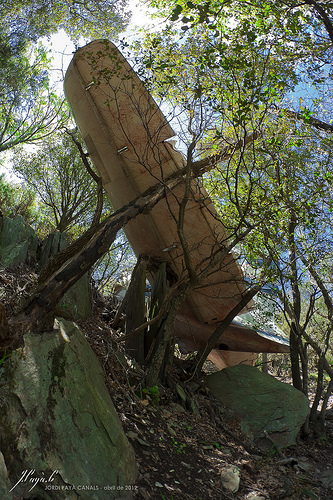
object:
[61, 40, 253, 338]
rock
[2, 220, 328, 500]
hillside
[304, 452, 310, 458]
leaves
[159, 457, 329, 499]
dirt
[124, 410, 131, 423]
leaves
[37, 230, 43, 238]
leaves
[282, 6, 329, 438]
tree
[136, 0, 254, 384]
tree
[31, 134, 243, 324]
tree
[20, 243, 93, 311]
trunk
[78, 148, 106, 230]
trunk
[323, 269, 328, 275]
leaf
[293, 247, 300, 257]
brances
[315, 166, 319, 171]
leaf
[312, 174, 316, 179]
leaf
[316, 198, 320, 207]
leaf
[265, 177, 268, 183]
leaf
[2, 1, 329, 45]
sky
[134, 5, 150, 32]
cloud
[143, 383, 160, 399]
mass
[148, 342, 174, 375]
base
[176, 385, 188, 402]
mass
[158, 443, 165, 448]
leaf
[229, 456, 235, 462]
leaf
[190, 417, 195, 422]
leaf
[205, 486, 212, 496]
leaf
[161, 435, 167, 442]
leaf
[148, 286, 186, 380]
trunk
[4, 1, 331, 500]
picture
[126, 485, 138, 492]
2012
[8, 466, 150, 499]
watermark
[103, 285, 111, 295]
weeds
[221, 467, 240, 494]
rock